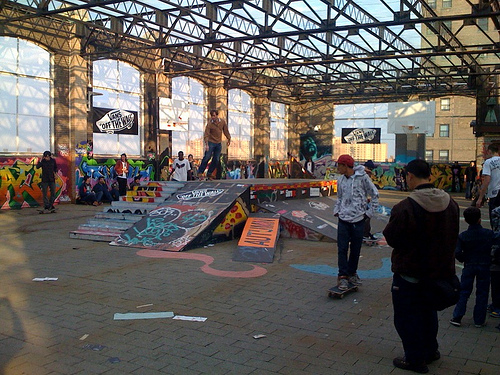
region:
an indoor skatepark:
[23, 46, 458, 327]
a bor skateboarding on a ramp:
[150, 85, 240, 252]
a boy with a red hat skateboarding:
[303, 151, 382, 321]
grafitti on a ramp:
[114, 176, 251, 259]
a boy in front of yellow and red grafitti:
[3, 150, 74, 221]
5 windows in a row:
[2, 34, 310, 164]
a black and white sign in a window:
[82, 99, 148, 143]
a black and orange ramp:
[230, 207, 290, 274]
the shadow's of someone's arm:
[0, 254, 62, 373]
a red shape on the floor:
[111, 246, 288, 287]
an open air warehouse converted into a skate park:
[4, 2, 491, 369]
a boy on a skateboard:
[323, 152, 378, 305]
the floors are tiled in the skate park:
[4, 202, 494, 373]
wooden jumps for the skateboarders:
[73, 172, 395, 270]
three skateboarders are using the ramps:
[163, 106, 323, 196]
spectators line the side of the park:
[381, 139, 498, 373]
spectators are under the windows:
[22, 149, 230, 210]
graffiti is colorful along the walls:
[4, 154, 481, 206]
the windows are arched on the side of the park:
[3, 20, 295, 178]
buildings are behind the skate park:
[194, 4, 497, 171]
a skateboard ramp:
[90, 172, 249, 257]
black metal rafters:
[24, 0, 499, 90]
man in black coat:
[378, 158, 459, 371]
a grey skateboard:
[310, 257, 376, 314]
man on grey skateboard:
[303, 145, 385, 332]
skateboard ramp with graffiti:
[112, 173, 250, 274]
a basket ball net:
[376, 91, 451, 151]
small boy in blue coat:
[454, 196, 499, 336]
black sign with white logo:
[85, 103, 156, 141]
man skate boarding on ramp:
[180, 103, 245, 231]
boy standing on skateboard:
[324, 151, 381, 303]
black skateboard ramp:
[111, 176, 251, 253]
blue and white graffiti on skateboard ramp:
[114, 206, 197, 251]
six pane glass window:
[0, 28, 59, 158]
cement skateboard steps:
[67, 174, 184, 240]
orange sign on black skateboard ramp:
[231, 211, 283, 264]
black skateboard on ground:
[323, 273, 365, 301]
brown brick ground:
[0, 265, 323, 374]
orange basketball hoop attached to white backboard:
[385, 102, 432, 139]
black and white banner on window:
[88, 103, 138, 135]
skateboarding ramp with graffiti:
[45, 146, 382, 306]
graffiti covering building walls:
[7, 150, 41, 217]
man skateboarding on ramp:
[181, 101, 229, 214]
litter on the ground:
[19, 253, 290, 345]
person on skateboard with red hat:
[312, 140, 387, 313]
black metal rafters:
[251, 5, 462, 99]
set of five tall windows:
[5, 76, 302, 163]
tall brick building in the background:
[424, 0, 498, 167]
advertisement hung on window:
[88, 100, 149, 136]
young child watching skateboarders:
[447, 200, 495, 325]